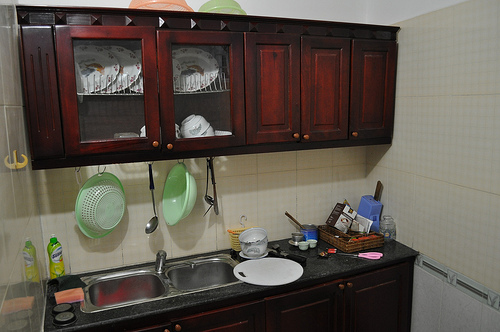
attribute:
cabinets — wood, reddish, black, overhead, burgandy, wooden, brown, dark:
[16, 5, 401, 171]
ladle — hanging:
[144, 164, 160, 235]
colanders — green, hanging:
[75, 162, 198, 239]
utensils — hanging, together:
[75, 158, 220, 241]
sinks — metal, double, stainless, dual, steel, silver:
[80, 248, 244, 314]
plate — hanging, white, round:
[233, 257, 304, 286]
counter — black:
[43, 237, 420, 331]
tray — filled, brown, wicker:
[320, 225, 385, 251]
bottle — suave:
[46, 236, 66, 280]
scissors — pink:
[336, 249, 383, 261]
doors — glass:
[54, 25, 245, 155]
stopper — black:
[50, 302, 76, 327]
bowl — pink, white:
[129, 0, 194, 10]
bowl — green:
[199, 0, 247, 17]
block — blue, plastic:
[357, 195, 384, 234]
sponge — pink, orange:
[54, 287, 86, 307]